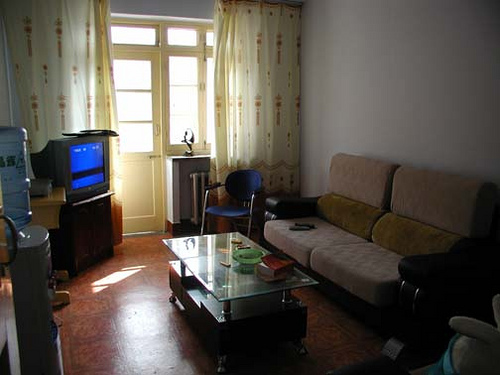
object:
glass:
[161, 231, 319, 302]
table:
[154, 219, 318, 367]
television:
[29, 137, 110, 204]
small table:
[50, 202, 125, 276]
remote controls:
[294, 223, 316, 229]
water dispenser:
[0, 225, 63, 374]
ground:
[421, 177, 447, 202]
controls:
[289, 226, 310, 230]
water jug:
[0, 123, 32, 240]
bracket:
[149, 155, 161, 159]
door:
[107, 16, 214, 239]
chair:
[200, 170, 263, 239]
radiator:
[188, 172, 208, 225]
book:
[257, 253, 296, 277]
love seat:
[262, 146, 500, 318]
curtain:
[0, 1, 122, 247]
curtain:
[204, 0, 303, 232]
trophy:
[182, 128, 196, 157]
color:
[69, 142, 103, 191]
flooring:
[76, 289, 161, 367]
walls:
[301, 5, 494, 212]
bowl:
[231, 249, 265, 265]